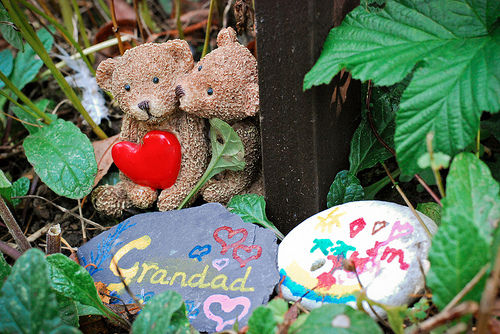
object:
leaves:
[0, 170, 30, 208]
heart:
[387, 221, 414, 242]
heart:
[189, 244, 212, 262]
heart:
[111, 130, 181, 190]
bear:
[90, 38, 208, 218]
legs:
[217, 131, 259, 194]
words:
[150, 268, 169, 284]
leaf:
[302, 1, 500, 183]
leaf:
[327, 170, 365, 208]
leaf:
[348, 71, 414, 176]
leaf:
[1, 245, 58, 334]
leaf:
[43, 252, 131, 327]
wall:
[154, 73, 225, 128]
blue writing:
[82, 220, 137, 275]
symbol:
[112, 131, 182, 190]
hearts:
[211, 257, 230, 271]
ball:
[77, 201, 280, 333]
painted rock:
[276, 200, 438, 322]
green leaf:
[178, 117, 246, 209]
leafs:
[416, 201, 443, 227]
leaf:
[426, 213, 490, 324]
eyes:
[207, 88, 213, 95]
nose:
[138, 100, 150, 110]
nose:
[175, 85, 185, 97]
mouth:
[139, 115, 165, 122]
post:
[254, 0, 362, 242]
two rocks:
[76, 200, 438, 332]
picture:
[305, 210, 409, 293]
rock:
[75, 203, 279, 333]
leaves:
[289, 304, 381, 334]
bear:
[175, 26, 264, 212]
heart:
[203, 294, 251, 332]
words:
[137, 263, 159, 283]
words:
[349, 217, 366, 239]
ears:
[162, 38, 195, 73]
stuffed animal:
[174, 26, 266, 207]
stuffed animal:
[90, 39, 209, 217]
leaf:
[227, 192, 287, 240]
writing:
[109, 235, 151, 278]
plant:
[307, 0, 484, 308]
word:
[211, 273, 228, 291]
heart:
[213, 226, 248, 256]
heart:
[232, 244, 262, 268]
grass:
[2, 1, 224, 137]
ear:
[217, 27, 240, 47]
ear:
[243, 83, 261, 116]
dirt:
[4, 92, 135, 263]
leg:
[113, 169, 133, 204]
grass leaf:
[22, 118, 97, 199]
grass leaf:
[9, 25, 56, 110]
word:
[380, 246, 410, 271]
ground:
[2, 2, 497, 332]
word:
[170, 271, 188, 287]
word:
[310, 238, 333, 256]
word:
[229, 266, 254, 292]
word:
[314, 207, 346, 233]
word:
[187, 265, 210, 289]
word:
[330, 240, 356, 259]